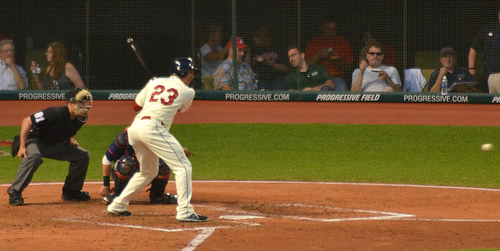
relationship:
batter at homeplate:
[107, 56, 209, 221] [216, 208, 263, 225]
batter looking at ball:
[107, 56, 209, 221] [478, 139, 493, 157]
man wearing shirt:
[103, 55, 209, 222] [133, 73, 197, 120]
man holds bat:
[103, 55, 209, 222] [122, 30, 154, 78]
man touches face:
[0, 35, 32, 102] [434, 47, 464, 74]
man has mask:
[9, 83, 96, 203] [73, 86, 95, 118]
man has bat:
[103, 55, 209, 222] [127, 35, 152, 76]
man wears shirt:
[274, 40, 332, 99] [281, 66, 326, 96]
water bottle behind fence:
[436, 72, 451, 99] [4, 92, 498, 132]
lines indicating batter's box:
[232, 191, 426, 249] [228, 189, 406, 236]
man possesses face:
[9, 83, 96, 203] [56, 74, 99, 112]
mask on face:
[73, 90, 93, 122] [56, 74, 99, 112]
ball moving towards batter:
[478, 139, 493, 157] [104, 32, 208, 214]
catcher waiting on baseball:
[106, 103, 210, 214] [457, 123, 495, 161]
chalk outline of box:
[52, 207, 259, 233] [83, 187, 293, 248]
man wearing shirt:
[9, 83, 96, 203] [20, 87, 104, 156]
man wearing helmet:
[103, 55, 209, 222] [168, 51, 200, 82]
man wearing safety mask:
[9, 83, 96, 203] [64, 86, 94, 115]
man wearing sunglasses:
[352, 40, 402, 91] [368, 50, 383, 56]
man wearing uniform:
[9, 58, 97, 248] [5, 68, 110, 210]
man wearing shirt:
[274, 40, 332, 99] [303, 38, 358, 75]